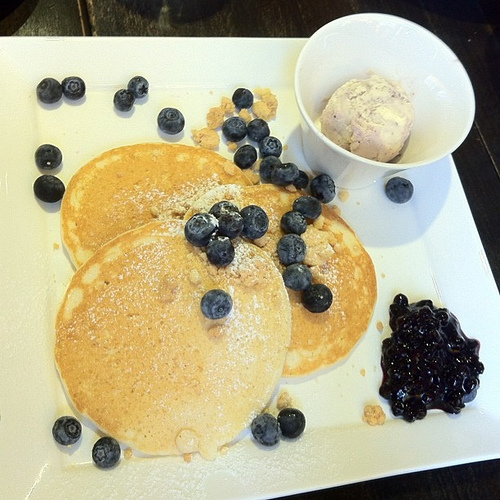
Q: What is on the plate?
A: Food.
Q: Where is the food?
A: On the plate.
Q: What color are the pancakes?
A: Gold.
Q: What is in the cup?
A: Ice cream.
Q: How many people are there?
A: None.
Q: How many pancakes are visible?
A: Three.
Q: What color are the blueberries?
A: Blue.